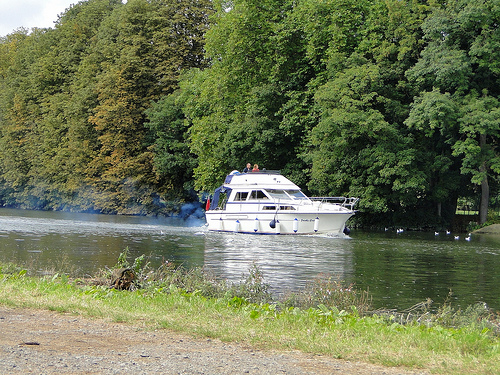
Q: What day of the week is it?
A: Monday.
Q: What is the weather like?
A: Sunny.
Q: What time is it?
A: Noon.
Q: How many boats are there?
A: One.